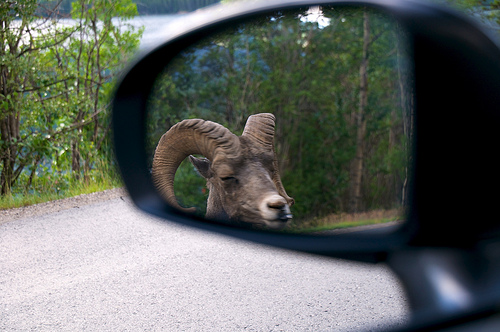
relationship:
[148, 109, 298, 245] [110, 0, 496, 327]
goat in mirror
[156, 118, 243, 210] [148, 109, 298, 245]
horn on a goat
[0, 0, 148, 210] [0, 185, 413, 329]
trees along road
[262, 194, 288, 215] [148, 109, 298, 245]
nose on a goat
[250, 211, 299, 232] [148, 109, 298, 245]
mouth on a goat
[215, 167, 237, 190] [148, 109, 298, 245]
eye of a goat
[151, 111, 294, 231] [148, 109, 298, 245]
ear of a goat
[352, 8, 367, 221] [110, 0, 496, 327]
tree trunk in mirror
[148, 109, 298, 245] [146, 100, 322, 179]
goat has horns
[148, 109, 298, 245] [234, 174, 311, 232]
goat has snout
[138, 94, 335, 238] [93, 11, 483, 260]
head in mirror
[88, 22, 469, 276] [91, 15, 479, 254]
mirror on car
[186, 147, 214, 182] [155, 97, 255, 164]
ear under horn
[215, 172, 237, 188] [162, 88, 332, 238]
eye on ram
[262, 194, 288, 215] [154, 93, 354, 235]
nose on ram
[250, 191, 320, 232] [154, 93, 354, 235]
mouth on ram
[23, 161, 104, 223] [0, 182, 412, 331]
grass alongside road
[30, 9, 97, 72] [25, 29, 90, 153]
water behind trees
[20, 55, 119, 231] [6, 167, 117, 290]
trees along road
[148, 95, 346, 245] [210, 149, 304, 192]
goat with eyes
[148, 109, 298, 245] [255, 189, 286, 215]
goat has a snout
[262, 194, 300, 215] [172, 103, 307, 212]
nose black on ram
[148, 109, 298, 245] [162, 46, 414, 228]
goat in a mirror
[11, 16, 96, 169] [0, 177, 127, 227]
bushes are on roadside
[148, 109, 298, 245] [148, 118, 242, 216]
goat has horn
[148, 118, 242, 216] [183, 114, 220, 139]
horn have ridges